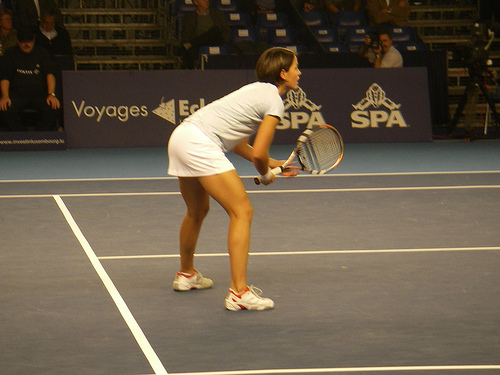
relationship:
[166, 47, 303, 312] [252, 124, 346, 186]
woman with racket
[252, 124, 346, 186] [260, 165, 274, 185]
racket in hand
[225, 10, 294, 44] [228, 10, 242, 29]
group of empty chair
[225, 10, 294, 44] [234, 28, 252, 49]
group of empty chair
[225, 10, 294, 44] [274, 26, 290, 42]
group of empty chair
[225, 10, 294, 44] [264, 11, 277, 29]
group of empty chair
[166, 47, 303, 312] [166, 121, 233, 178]
woman wearing white skirt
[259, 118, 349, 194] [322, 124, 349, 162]
racket has top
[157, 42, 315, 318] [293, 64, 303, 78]
woman has nose